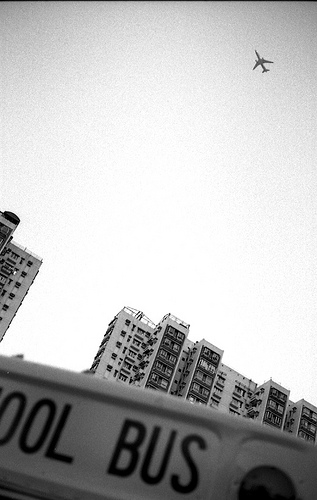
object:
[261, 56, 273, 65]
wing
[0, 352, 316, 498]
bus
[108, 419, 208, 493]
word bus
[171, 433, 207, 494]
letter s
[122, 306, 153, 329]
roof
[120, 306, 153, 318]
bars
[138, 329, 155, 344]
windows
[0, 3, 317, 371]
overcast sky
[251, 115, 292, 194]
ground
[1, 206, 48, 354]
building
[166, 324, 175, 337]
window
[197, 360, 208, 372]
window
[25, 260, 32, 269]
window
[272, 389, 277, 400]
window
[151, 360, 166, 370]
window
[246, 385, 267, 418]
balconies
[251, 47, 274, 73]
airplane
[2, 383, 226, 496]
letter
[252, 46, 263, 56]
nose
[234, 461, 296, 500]
light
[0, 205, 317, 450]
building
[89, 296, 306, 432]
building